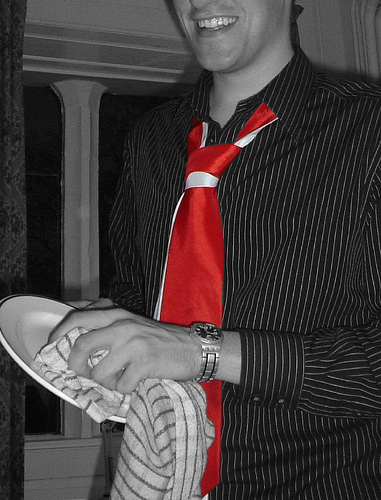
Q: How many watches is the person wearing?
A: One.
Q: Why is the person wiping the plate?
A: To clean it.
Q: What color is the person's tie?
A: Red and white.